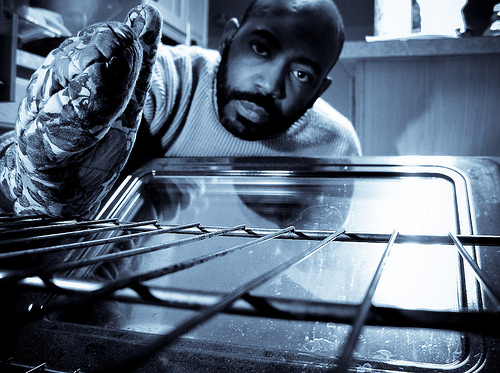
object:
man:
[25, 0, 354, 225]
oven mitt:
[0, 2, 162, 219]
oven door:
[38, 156, 498, 370]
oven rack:
[0, 212, 499, 373]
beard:
[220, 42, 313, 139]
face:
[218, 0, 330, 134]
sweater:
[145, 50, 355, 156]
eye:
[249, 41, 271, 57]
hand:
[18, 14, 161, 205]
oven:
[6, 141, 497, 372]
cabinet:
[354, 49, 496, 156]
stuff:
[0, 6, 69, 42]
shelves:
[0, 2, 97, 104]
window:
[372, 0, 499, 43]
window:
[81, 171, 456, 338]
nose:
[254, 54, 288, 99]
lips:
[231, 100, 269, 119]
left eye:
[290, 68, 311, 85]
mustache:
[216, 41, 314, 137]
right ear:
[218, 18, 240, 50]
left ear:
[307, 76, 331, 109]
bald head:
[245, 1, 349, 68]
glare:
[347, 163, 488, 314]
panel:
[360, 58, 494, 155]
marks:
[267, 315, 482, 370]